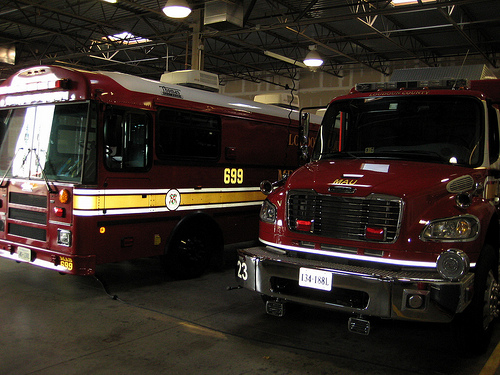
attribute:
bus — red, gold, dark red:
[4, 58, 338, 282]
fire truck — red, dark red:
[236, 75, 498, 336]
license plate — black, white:
[298, 267, 335, 292]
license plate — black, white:
[15, 246, 37, 265]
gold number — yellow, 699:
[224, 164, 245, 187]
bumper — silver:
[236, 261, 472, 326]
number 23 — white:
[236, 262, 249, 281]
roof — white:
[77, 91, 292, 108]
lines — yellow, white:
[94, 192, 262, 205]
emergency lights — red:
[369, 226, 385, 241]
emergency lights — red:
[297, 220, 310, 231]